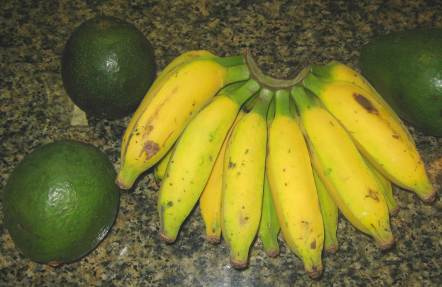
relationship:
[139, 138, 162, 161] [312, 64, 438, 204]
spot on banana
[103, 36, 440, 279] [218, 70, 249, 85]
bananas has stem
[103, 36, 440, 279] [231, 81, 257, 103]
bananas has stem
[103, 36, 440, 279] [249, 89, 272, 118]
bananas has stem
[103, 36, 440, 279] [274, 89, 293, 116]
bananas has stem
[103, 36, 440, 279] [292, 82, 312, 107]
bananas has stem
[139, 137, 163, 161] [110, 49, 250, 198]
spot on banana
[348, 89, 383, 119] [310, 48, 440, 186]
patch on banana.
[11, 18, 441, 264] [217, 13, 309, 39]
fruit on counter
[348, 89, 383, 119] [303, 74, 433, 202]
patch on banana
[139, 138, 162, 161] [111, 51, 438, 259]
spot on banana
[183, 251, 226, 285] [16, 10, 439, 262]
reflection on table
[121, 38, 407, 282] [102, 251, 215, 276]
fruit on countertop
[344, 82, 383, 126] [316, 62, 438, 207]
patch on banana